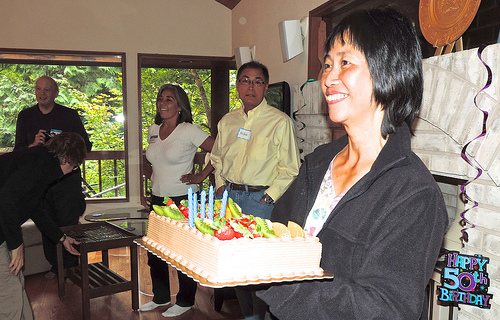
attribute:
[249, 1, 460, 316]
woman — smiling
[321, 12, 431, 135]
hair — black, shiny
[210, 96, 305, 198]
shirt — yellow, long sleeved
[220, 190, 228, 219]
candle — blue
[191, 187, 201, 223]
candle — blue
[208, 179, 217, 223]
candle — blue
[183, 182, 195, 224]
candle — blue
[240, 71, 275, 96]
glasses — black rimmed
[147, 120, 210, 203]
shirt — white